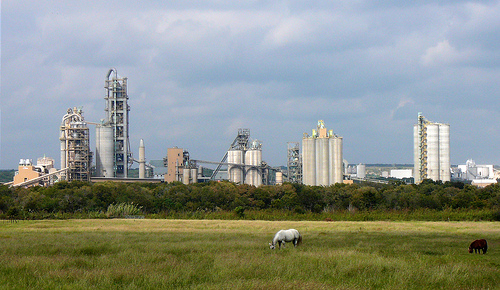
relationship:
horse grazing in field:
[267, 227, 304, 249] [10, 218, 259, 282]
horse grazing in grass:
[267, 227, 304, 250] [1, 217, 499, 288]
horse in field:
[267, 227, 304, 249] [2, 215, 498, 289]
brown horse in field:
[463, 238, 487, 255] [2, 215, 498, 289]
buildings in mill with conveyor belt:
[159, 137, 211, 203] [185, 139, 284, 176]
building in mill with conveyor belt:
[222, 129, 267, 188] [185, 139, 284, 176]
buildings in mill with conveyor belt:
[278, 110, 349, 211] [185, 139, 284, 176]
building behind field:
[222, 129, 263, 192] [6, 186, 498, 288]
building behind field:
[261, 123, 497, 220] [368, 225, 424, 277]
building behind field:
[94, 66, 132, 183] [45, 220, 267, 277]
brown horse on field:
[453, 227, 488, 255] [36, 222, 490, 288]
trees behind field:
[0, 178, 499, 221] [29, 220, 494, 277]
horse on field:
[267, 227, 304, 249] [106, 210, 242, 285]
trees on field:
[0, 178, 499, 218] [2, 215, 498, 289]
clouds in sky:
[148, 11, 268, 71] [237, 27, 363, 124]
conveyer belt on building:
[210, 130, 237, 175] [222, 129, 267, 188]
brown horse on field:
[463, 238, 487, 255] [2, 215, 498, 289]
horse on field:
[267, 227, 304, 250] [2, 215, 498, 289]